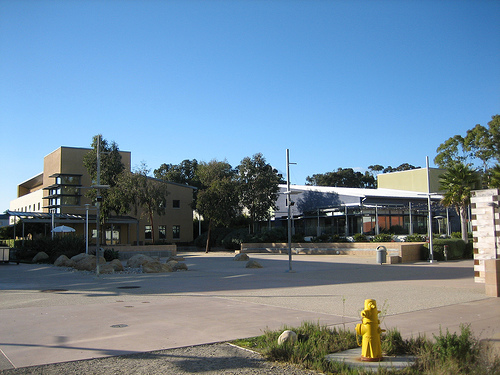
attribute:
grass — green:
[298, 327, 333, 368]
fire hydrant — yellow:
[353, 298, 388, 362]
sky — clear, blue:
[179, 56, 429, 118]